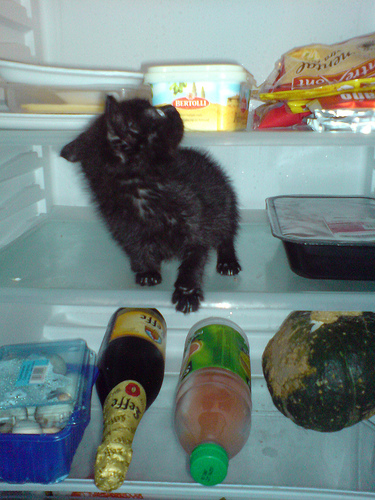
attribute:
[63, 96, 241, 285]
kitten — black, small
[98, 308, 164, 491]
bottle — sealed, green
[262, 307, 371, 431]
squash — green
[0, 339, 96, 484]
box — blue, square, colored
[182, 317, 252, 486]
bottle — clear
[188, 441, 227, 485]
lid — green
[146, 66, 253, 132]
dish — yellow, white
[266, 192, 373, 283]
box — square, black, sealed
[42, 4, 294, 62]
interior — white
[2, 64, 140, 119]
container — plastic, small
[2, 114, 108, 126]
plate — white, yellow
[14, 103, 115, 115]
food — yellow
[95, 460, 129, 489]
foil — gold